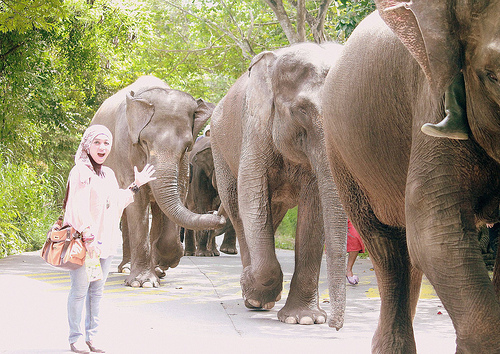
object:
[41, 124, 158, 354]
woman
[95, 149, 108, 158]
mouth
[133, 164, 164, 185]
hand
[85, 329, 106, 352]
shoe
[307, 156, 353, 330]
trunk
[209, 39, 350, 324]
elephant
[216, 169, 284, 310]
leg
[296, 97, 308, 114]
eye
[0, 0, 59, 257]
plant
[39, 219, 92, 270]
bag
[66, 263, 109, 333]
jeans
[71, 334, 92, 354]
shoes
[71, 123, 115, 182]
scarf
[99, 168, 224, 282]
path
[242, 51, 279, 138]
ear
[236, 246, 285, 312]
foot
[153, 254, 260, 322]
concrete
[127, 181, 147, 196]
bracelet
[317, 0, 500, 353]
elephants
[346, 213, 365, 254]
cloth